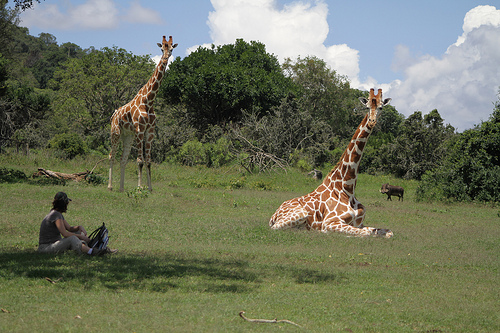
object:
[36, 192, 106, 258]
man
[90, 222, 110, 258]
backpack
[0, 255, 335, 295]
shadow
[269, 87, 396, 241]
giraffe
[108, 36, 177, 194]
giraffe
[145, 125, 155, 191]
leg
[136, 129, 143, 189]
leg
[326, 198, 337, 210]
brown spot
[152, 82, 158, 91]
brown spot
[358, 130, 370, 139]
spot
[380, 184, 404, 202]
boar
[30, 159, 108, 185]
dead tree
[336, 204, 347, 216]
spot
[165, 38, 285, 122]
tree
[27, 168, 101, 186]
wood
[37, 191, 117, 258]
woman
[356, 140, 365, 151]
brown spot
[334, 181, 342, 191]
brown spot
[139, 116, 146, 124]
brown spot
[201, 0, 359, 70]
cloud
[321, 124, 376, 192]
giraffe neck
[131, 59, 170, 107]
giraffe neck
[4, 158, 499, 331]
field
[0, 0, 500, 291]
vegetation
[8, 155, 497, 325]
ground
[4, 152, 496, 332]
grass